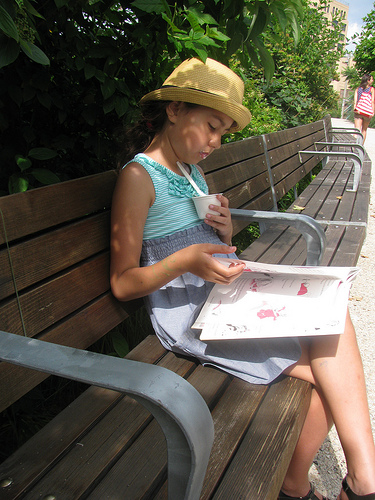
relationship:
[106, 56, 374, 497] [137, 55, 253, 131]
girl wearing hat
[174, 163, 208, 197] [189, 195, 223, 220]
spoon in container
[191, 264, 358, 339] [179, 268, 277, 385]
book on lap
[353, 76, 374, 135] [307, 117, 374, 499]
woman down sidewalk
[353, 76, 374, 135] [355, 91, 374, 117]
woman has bag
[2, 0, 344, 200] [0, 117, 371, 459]
trees behind benches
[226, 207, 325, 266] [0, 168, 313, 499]
armrest on bench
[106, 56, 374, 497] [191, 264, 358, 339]
girl reading book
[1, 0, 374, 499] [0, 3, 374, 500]
photo in city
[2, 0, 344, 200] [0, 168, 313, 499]
trees behind bench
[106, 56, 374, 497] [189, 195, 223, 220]
girl holding container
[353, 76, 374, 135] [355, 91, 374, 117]
woman carrying bag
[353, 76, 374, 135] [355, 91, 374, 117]
woman holding bag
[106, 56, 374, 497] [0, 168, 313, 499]
girl on bench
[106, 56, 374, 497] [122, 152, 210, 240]
girl wearing top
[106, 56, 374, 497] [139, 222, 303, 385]
girl wearing skirt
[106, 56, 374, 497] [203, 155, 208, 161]
girl with food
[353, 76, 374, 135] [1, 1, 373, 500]
woman in park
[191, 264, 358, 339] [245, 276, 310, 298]
book with pictures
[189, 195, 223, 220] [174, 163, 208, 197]
container has spoon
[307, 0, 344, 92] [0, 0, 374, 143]
building in background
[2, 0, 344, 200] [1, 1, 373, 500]
trees in park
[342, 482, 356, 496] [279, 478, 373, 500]
part of sandals